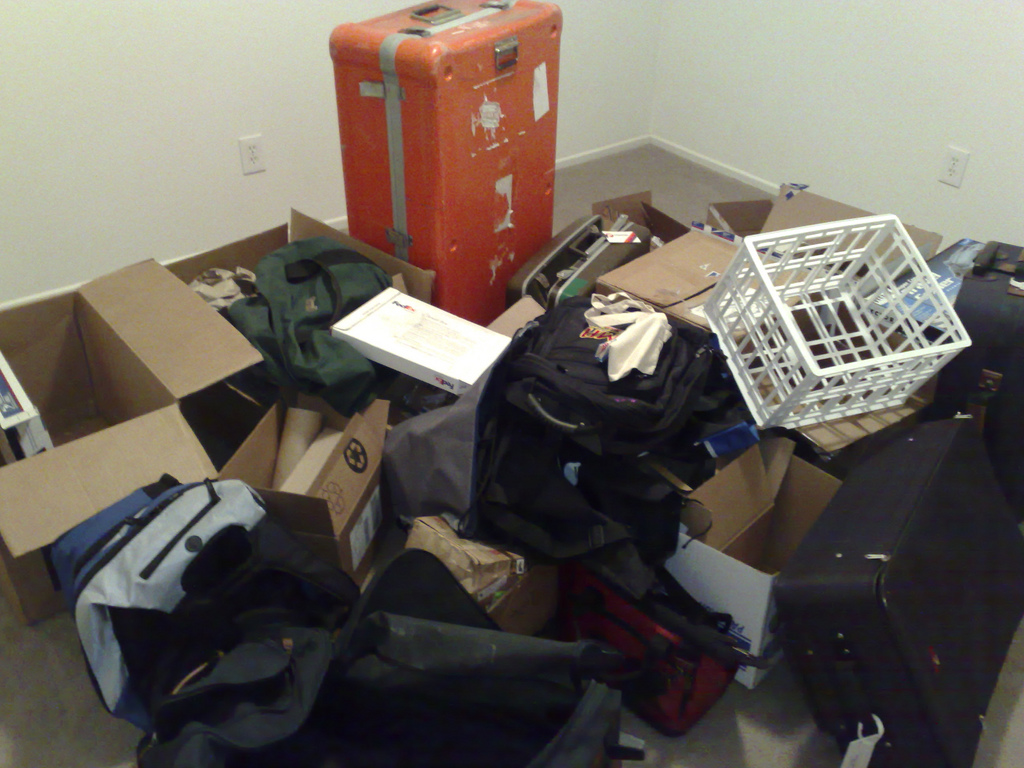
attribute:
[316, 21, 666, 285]
case — orange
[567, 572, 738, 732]
hand bag — red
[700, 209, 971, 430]
plastic container — empty, white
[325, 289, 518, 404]
fedex box — white, small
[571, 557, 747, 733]
bag — small, black and red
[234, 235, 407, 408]
duffel bag — empty, green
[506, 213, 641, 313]
brown suitcase — partly open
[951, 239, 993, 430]
suitcase — dark blue, one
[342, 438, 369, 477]
recycle sign — small, circle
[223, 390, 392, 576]
box — brown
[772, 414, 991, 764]
suitcase — one, dark blue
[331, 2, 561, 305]
suitcase — large, orange, hard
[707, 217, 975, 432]
small basket — white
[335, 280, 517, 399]
shipping box — small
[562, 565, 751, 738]
red bag — small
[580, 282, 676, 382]
paper — wadded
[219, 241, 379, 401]
empty bag — green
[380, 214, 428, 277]
stripe — silver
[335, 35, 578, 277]
suitcase — orange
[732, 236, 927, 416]
box — empty, white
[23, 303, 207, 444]
box — open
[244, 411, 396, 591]
box — small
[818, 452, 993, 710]
suitcase — black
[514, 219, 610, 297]
suitcase — open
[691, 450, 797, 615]
box — open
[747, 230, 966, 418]
crate — white, plastic